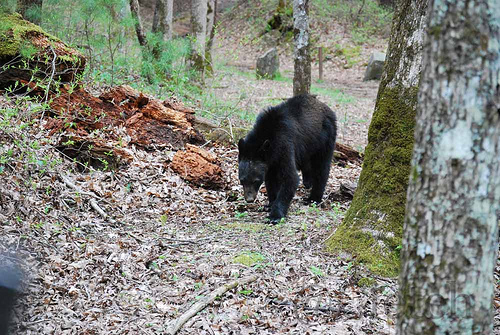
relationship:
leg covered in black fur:
[308, 166, 331, 203] [319, 173, 323, 182]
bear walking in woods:
[224, 90, 339, 226] [62, 3, 194, 110]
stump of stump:
[253, 42, 280, 77] [253, 42, 280, 77]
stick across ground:
[159, 262, 265, 334] [119, 225, 200, 285]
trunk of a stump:
[253, 42, 280, 77] [253, 42, 280, 77]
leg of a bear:
[308, 166, 331, 203] [224, 90, 339, 226]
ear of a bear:
[259, 140, 276, 154] [224, 90, 339, 226]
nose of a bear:
[245, 192, 258, 204] [224, 90, 339, 226]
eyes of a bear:
[239, 173, 262, 188] [224, 90, 339, 226]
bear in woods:
[224, 90, 339, 226] [62, 3, 194, 110]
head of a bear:
[234, 136, 272, 203] [224, 90, 339, 226]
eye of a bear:
[254, 178, 260, 188] [224, 90, 339, 226]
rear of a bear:
[308, 96, 344, 146] [224, 90, 339, 226]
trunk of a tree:
[253, 42, 280, 77] [9, 15, 170, 152]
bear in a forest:
[224, 90, 339, 226] [28, 11, 214, 188]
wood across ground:
[176, 145, 221, 185] [119, 225, 200, 285]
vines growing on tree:
[79, 3, 138, 48] [9, 15, 170, 152]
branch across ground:
[31, 55, 54, 127] [119, 225, 200, 285]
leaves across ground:
[188, 244, 219, 277] [119, 225, 200, 285]